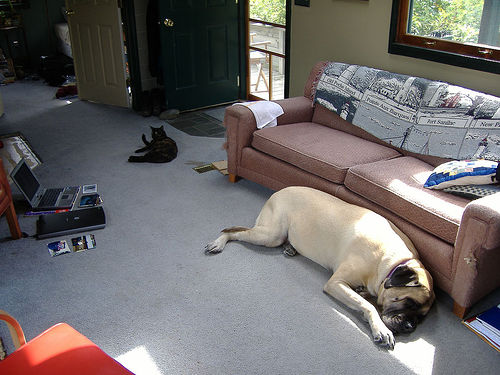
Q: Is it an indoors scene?
A: Yes, it is indoors.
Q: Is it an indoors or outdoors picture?
A: It is indoors.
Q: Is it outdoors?
A: No, it is indoors.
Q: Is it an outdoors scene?
A: No, it is indoors.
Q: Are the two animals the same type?
A: No, they are dogs and cats.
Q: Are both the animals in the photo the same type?
A: No, they are dogs and cats.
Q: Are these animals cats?
A: No, they are dogs and cats.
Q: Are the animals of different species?
A: Yes, they are dogs and cats.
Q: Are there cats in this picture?
A: Yes, there is a cat.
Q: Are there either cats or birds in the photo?
A: Yes, there is a cat.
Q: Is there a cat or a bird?
A: Yes, there is a cat.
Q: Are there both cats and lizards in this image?
A: No, there is a cat but no lizards.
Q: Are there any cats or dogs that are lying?
A: Yes, the cat is lying.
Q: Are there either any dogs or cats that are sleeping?
A: Yes, the cat is sleeping.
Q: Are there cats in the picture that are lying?
A: Yes, there is a cat that is lying.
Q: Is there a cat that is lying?
A: Yes, there is a cat that is lying.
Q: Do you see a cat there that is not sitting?
A: Yes, there is a cat that is lying .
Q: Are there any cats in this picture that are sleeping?
A: Yes, there is a cat that is sleeping.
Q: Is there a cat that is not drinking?
A: Yes, there is a cat that is sleeping.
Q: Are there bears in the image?
A: No, there are no bears.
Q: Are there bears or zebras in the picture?
A: No, there are no bears or zebras.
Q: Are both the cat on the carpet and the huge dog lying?
A: Yes, both the cat and the dog are lying.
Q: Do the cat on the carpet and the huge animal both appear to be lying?
A: Yes, both the cat and the dog are lying.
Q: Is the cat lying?
A: Yes, the cat is lying.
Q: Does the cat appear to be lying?
A: Yes, the cat is lying.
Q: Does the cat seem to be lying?
A: Yes, the cat is lying.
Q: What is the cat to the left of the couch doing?
A: The cat is lying.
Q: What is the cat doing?
A: The cat is lying.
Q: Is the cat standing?
A: No, the cat is lying.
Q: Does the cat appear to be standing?
A: No, the cat is lying.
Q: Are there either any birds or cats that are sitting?
A: No, there is a cat but it is lying.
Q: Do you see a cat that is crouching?
A: No, there is a cat but it is lying.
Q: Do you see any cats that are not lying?
A: No, there is a cat but it is lying.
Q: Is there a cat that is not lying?
A: No, there is a cat but it is lying.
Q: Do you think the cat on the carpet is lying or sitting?
A: The cat is lying.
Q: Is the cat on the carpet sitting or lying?
A: The cat is lying.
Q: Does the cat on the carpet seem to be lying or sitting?
A: The cat is lying.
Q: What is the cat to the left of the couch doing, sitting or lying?
A: The cat is lying.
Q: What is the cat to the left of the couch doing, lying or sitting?
A: The cat is lying.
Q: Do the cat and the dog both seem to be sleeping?
A: Yes, both the cat and the dog are sleeping.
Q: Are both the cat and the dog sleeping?
A: Yes, both the cat and the dog are sleeping.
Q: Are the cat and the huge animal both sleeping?
A: Yes, both the cat and the dog are sleeping.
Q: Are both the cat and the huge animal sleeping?
A: Yes, both the cat and the dog are sleeping.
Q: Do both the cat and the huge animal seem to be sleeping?
A: Yes, both the cat and the dog are sleeping.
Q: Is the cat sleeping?
A: Yes, the cat is sleeping.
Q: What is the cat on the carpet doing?
A: The cat is sleeping.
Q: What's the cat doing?
A: The cat is sleeping.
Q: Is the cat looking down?
A: No, the cat is sleeping.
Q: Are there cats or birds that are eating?
A: No, there is a cat but it is sleeping.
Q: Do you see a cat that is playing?
A: No, there is a cat but it is sleeping.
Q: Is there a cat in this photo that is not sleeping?
A: No, there is a cat but it is sleeping.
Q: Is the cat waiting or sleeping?
A: The cat is sleeping.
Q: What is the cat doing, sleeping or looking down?
A: The cat is sleeping.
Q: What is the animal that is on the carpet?
A: The animal is a cat.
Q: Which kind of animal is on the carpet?
A: The animal is a cat.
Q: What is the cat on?
A: The cat is on the carpet.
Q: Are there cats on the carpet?
A: Yes, there is a cat on the carpet.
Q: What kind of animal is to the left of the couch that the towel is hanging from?
A: The animal is a cat.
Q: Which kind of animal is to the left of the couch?
A: The animal is a cat.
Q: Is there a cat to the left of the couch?
A: Yes, there is a cat to the left of the couch.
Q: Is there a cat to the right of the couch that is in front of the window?
A: No, the cat is to the left of the couch.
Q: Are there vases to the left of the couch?
A: No, there is a cat to the left of the couch.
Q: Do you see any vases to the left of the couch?
A: No, there is a cat to the left of the couch.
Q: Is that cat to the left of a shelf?
A: No, the cat is to the left of a couch.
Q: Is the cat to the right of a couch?
A: No, the cat is to the left of a couch.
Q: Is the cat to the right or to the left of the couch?
A: The cat is to the left of the couch.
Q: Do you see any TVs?
A: No, there are no tvs.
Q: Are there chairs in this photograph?
A: Yes, there is a chair.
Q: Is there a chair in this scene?
A: Yes, there is a chair.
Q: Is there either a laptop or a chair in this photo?
A: Yes, there is a chair.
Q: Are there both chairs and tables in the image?
A: No, there is a chair but no tables.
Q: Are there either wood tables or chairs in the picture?
A: Yes, there is a wood chair.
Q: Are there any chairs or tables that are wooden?
A: Yes, the chair is wooden.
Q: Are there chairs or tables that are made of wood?
A: Yes, the chair is made of wood.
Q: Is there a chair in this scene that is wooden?
A: Yes, there is a wood chair.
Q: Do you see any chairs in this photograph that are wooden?
A: Yes, there is a chair that is wooden.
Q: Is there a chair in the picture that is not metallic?
A: Yes, there is a wooden chair.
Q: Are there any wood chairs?
A: Yes, there is a chair that is made of wood.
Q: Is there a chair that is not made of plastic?
A: Yes, there is a chair that is made of wood.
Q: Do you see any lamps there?
A: No, there are no lamps.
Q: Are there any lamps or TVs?
A: No, there are no lamps or tvs.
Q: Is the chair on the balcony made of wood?
A: Yes, the chair is made of wood.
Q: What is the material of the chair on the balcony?
A: The chair is made of wood.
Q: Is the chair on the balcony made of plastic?
A: No, the chair is made of wood.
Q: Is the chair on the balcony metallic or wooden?
A: The chair is wooden.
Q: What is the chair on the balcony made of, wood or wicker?
A: The chair is made of wood.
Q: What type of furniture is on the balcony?
A: The piece of furniture is a chair.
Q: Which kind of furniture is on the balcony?
A: The piece of furniture is a chair.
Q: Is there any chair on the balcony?
A: Yes, there is a chair on the balcony.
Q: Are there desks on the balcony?
A: No, there is a chair on the balcony.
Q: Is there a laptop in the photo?
A: Yes, there is a laptop.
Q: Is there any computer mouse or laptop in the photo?
A: Yes, there is a laptop.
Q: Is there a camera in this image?
A: No, there are no cameras.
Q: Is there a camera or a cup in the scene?
A: No, there are no cameras or cups.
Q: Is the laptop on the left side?
A: Yes, the laptop is on the left of the image.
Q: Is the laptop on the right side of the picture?
A: No, the laptop is on the left of the image.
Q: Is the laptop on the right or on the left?
A: The laptop is on the left of the image.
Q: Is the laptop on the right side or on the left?
A: The laptop is on the left of the image.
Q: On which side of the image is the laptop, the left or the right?
A: The laptop is on the left of the image.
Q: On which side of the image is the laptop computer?
A: The laptop computer is on the left of the image.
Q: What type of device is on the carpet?
A: The device is a laptop.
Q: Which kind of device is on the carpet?
A: The device is a laptop.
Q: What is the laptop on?
A: The laptop is on the carpet.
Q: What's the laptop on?
A: The laptop is on the carpet.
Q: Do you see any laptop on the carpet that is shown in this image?
A: Yes, there is a laptop on the carpet.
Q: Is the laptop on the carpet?
A: Yes, the laptop is on the carpet.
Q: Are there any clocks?
A: No, there are no clocks.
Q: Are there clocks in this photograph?
A: No, there are no clocks.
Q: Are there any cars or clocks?
A: No, there are no clocks or cars.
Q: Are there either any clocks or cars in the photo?
A: No, there are no clocks or cars.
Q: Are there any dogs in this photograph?
A: Yes, there is a dog.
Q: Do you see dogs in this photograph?
A: Yes, there is a dog.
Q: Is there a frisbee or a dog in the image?
A: Yes, there is a dog.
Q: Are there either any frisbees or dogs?
A: Yes, there is a dog.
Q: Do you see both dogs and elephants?
A: No, there is a dog but no elephants.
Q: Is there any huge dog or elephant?
A: Yes, there is a huge dog.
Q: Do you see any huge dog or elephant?
A: Yes, there is a huge dog.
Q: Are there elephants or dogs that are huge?
A: Yes, the dog is huge.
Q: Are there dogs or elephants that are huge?
A: Yes, the dog is huge.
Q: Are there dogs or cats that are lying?
A: Yes, the dog is lying.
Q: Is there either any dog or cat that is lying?
A: Yes, the dog is lying.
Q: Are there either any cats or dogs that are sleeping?
A: Yes, the dog is sleeping.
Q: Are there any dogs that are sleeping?
A: Yes, there is a dog that is sleeping.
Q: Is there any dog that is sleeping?
A: Yes, there is a dog that is sleeping.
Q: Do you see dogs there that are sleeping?
A: Yes, there is a dog that is sleeping.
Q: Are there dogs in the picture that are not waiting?
A: Yes, there is a dog that is sleeping.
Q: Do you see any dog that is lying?
A: Yes, there is a dog that is lying.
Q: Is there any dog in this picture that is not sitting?
A: Yes, there is a dog that is lying.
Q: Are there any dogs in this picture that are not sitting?
A: Yes, there is a dog that is lying.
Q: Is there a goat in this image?
A: No, there are no goats.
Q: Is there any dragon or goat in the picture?
A: No, there are no goats or dragons.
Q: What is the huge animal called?
A: The animal is a dog.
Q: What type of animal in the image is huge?
A: The animal is a dog.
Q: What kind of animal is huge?
A: The animal is a dog.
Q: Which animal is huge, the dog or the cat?
A: The dog is huge.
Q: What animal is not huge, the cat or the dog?
A: The cat is not huge.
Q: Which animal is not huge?
A: The animal is a cat.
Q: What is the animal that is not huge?
A: The animal is a cat.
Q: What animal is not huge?
A: The animal is a cat.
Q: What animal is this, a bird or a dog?
A: This is a dog.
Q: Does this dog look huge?
A: Yes, the dog is huge.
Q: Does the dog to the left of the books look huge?
A: Yes, the dog is huge.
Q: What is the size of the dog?
A: The dog is huge.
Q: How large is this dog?
A: The dog is huge.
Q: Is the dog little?
A: No, the dog is huge.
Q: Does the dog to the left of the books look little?
A: No, the dog is huge.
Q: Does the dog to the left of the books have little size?
A: No, the dog is huge.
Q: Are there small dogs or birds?
A: No, there is a dog but it is huge.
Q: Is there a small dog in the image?
A: No, there is a dog but it is huge.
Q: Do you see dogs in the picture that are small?
A: No, there is a dog but it is huge.